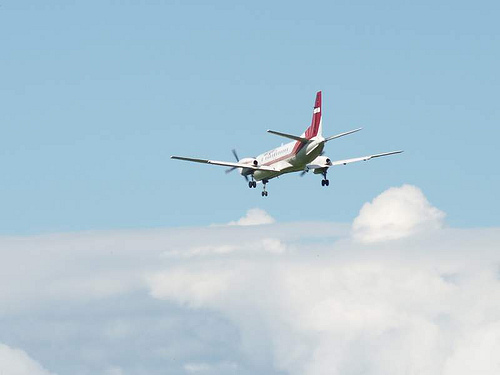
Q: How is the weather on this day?
A: It is cloudy.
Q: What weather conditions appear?
A: It is cloudy.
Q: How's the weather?
A: It is cloudy.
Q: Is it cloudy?
A: Yes, it is cloudy.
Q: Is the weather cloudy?
A: Yes, it is cloudy.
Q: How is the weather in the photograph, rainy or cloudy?
A: It is cloudy.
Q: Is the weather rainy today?
A: No, it is cloudy.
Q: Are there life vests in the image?
A: No, there are no life vests.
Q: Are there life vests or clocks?
A: No, there are no life vests or clocks.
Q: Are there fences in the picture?
A: No, there are no fences.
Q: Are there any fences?
A: No, there are no fences.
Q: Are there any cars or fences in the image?
A: No, there are no fences or cars.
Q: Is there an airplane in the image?
A: Yes, there is an airplane.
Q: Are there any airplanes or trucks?
A: Yes, there is an airplane.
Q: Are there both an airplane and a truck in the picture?
A: No, there is an airplane but no trucks.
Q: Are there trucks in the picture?
A: No, there are no trucks.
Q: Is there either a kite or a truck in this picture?
A: No, there are no trucks or kites.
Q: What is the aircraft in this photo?
A: The aircraft is an airplane.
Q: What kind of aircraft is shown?
A: The aircraft is an airplane.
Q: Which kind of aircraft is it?
A: The aircraft is an airplane.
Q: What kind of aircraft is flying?
A: The aircraft is an airplane.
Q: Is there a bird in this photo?
A: No, there are no birds.